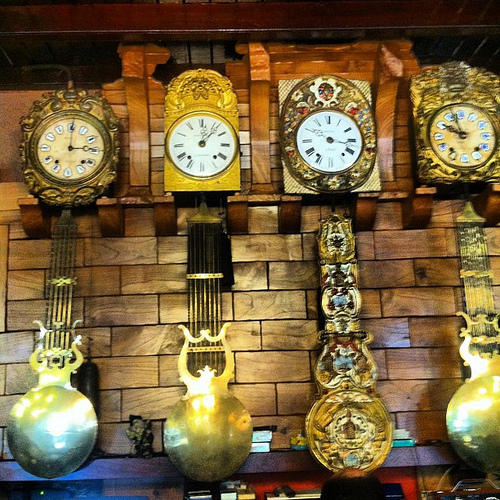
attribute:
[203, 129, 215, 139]
arm — long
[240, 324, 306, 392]
wall — brown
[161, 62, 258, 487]
clock — gold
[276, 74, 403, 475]
clock — large, decorative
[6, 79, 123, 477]
clock — large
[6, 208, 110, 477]
pendulum — decorative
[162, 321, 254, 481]
pendulum — shiny, gold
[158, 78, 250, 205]
clock — yellow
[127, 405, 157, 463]
gnome — small, scultpure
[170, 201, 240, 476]
pendulum — gold, long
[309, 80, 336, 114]
gemstones — colorful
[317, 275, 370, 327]
decoration — brown, blue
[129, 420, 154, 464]
figurine — gold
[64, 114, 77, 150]
hand — black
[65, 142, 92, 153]
hand — black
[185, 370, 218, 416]
spot — white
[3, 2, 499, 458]
wall — brick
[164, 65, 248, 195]
clock — gold